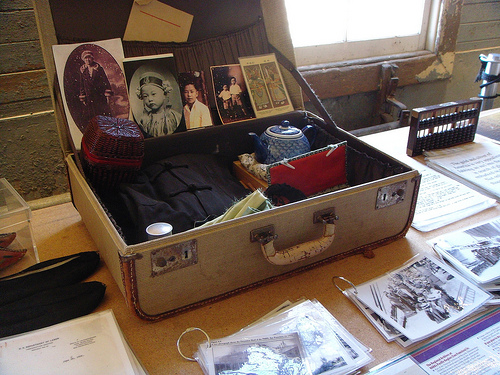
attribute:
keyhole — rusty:
[181, 242, 193, 262]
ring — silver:
[325, 280, 358, 302]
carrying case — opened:
[33, 6, 420, 316]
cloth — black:
[109, 149, 249, 242]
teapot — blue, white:
[244, 115, 326, 167]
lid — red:
[267, 140, 350, 190]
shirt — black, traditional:
[133, 149, 222, 216]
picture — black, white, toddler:
[68, 37, 125, 147]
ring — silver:
[174, 325, 211, 361]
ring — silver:
[331, 273, 358, 295]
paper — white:
[434, 141, 497, 197]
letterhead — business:
[13, 318, 150, 373]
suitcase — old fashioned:
[31, 0, 422, 322]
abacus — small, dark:
[391, 93, 492, 174]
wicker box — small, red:
[81, 109, 160, 181]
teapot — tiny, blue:
[247, 124, 322, 149]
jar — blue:
[251, 114, 311, 163]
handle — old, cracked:
[251, 208, 341, 266]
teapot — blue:
[238, 115, 318, 167]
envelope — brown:
[113, 3, 185, 46]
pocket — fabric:
[58, 26, 268, 113]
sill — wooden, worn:
[305, 47, 463, 99]